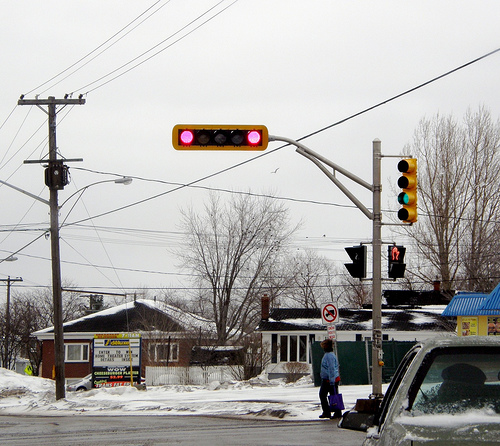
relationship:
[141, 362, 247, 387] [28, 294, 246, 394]
fence in front of building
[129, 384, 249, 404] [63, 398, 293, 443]
snow covering ground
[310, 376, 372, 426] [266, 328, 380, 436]
pants on woman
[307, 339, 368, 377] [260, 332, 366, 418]
jacket on woman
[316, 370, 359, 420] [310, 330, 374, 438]
bag on woman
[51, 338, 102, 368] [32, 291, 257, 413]
window on building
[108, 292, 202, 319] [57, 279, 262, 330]
snow on roof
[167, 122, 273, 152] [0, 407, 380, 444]
light hanging over street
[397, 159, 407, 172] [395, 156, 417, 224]
light in light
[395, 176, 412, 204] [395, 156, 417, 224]
light in light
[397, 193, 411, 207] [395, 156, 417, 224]
light in light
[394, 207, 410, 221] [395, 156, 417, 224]
light in light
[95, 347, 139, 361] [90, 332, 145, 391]
lettering on sign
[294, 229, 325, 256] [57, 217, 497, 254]
birds on lines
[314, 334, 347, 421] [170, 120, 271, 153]
person walking under light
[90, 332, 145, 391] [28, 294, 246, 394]
sign in front of building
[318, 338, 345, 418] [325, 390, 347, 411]
person carrying bag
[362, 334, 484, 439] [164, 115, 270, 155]
car at light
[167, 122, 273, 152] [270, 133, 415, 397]
light connected to post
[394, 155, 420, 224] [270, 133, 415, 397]
light connected to post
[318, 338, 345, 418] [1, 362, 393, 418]
person in snow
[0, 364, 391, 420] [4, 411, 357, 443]
snow on road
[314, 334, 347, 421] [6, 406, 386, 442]
person on road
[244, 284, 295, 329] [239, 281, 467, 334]
chimney on roof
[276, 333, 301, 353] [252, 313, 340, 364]
lines on window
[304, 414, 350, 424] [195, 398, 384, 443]
foot off ground